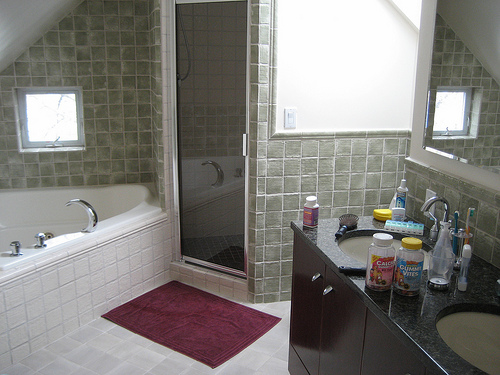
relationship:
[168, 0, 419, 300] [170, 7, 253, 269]
shower has door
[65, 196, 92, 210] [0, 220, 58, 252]
faucet on tub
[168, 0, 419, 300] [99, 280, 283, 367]
shower closed mat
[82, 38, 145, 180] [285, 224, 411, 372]
wall standing cabinet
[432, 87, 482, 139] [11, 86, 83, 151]
window sealed window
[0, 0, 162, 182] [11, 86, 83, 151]
wall tiled window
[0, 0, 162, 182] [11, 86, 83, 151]
wall standing window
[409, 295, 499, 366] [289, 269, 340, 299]
cabinet standing knobs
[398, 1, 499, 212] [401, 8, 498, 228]
mirror standing wall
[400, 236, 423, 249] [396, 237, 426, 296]
top closed bottles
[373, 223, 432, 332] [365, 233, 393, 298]
label adhered bottle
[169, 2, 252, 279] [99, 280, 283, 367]
shower door closed mat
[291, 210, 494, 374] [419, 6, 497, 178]
counter standing mirror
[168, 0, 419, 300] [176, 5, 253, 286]
shower closed door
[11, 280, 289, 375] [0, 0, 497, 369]
floor lying bathroom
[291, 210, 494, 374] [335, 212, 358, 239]
counter standing brush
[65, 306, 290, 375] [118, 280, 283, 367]
floor lying mat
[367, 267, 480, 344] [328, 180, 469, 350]
vanity standing vitamins